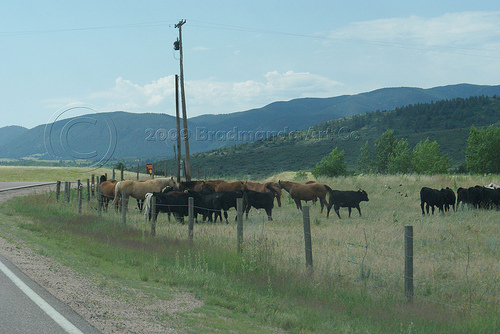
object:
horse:
[98, 174, 327, 197]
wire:
[2, 17, 496, 64]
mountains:
[0, 83, 499, 162]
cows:
[420, 185, 499, 214]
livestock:
[96, 179, 499, 221]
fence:
[56, 168, 497, 330]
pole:
[402, 224, 414, 305]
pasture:
[1, 166, 498, 333]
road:
[1, 180, 102, 333]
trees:
[293, 122, 499, 177]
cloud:
[43, 69, 355, 120]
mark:
[1, 260, 80, 333]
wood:
[302, 204, 312, 278]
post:
[170, 19, 193, 183]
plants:
[144, 231, 291, 322]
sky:
[1, 1, 497, 83]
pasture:
[89, 167, 497, 311]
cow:
[326, 189, 370, 219]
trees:
[132, 95, 497, 173]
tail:
[111, 181, 119, 209]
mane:
[151, 176, 176, 183]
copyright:
[42, 104, 361, 172]